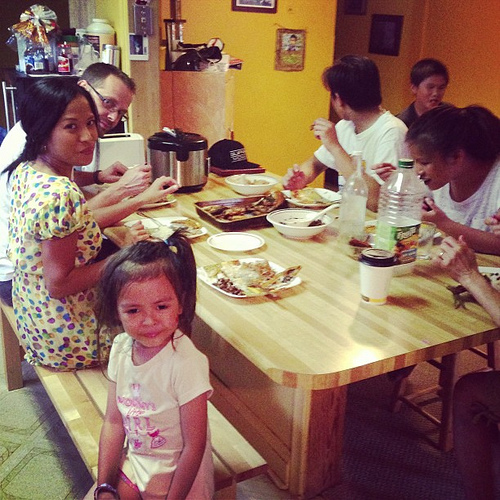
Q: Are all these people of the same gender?
A: No, they are both male and female.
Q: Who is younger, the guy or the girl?
A: The girl is younger than the guy.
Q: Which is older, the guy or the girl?
A: The guy is older than the girl.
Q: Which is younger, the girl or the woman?
A: The girl is younger than the woman.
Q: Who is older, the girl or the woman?
A: The woman is older than the girl.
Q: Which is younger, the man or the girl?
A: The girl is younger than the man.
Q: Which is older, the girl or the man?
A: The man is older than the girl.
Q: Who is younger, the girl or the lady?
A: The girl is younger than the lady.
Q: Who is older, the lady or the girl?
A: The lady is older than the girl.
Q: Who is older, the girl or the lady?
A: The lady is older than the girl.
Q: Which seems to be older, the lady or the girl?
A: The lady is older than the girl.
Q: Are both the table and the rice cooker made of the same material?
A: No, the table is made of wood and the rice cooker is made of metal.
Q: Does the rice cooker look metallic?
A: Yes, the rice cooker is metallic.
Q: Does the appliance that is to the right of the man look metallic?
A: Yes, the rice cooker is metallic.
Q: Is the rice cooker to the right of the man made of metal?
A: Yes, the rice cooker is made of metal.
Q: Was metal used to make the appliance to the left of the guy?
A: Yes, the rice cooker is made of metal.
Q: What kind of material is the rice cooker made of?
A: The rice cooker is made of metal.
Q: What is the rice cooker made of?
A: The rice cooker is made of metal.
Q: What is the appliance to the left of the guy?
A: The appliance is a rice cooker.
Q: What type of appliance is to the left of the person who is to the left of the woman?
A: The appliance is a rice cooker.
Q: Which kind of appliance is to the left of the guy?
A: The appliance is a rice cooker.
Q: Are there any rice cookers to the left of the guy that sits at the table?
A: Yes, there is a rice cooker to the left of the guy.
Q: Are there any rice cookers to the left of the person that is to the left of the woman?
A: Yes, there is a rice cooker to the left of the guy.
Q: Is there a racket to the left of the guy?
A: No, there is a rice cooker to the left of the guy.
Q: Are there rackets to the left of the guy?
A: No, there is a rice cooker to the left of the guy.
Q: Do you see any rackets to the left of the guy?
A: No, there is a rice cooker to the left of the guy.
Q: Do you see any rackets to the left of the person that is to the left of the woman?
A: No, there is a rice cooker to the left of the guy.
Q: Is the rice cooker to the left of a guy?
A: Yes, the rice cooker is to the left of a guy.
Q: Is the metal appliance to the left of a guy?
A: Yes, the rice cooker is to the left of a guy.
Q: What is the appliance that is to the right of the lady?
A: The appliance is a rice cooker.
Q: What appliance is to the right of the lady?
A: The appliance is a rice cooker.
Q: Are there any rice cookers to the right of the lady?
A: Yes, there is a rice cooker to the right of the lady.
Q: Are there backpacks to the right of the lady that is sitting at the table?
A: No, there is a rice cooker to the right of the lady.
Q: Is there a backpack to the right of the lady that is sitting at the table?
A: No, there is a rice cooker to the right of the lady.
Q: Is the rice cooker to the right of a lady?
A: Yes, the rice cooker is to the right of a lady.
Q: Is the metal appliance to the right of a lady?
A: Yes, the rice cooker is to the right of a lady.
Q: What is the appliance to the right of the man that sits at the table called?
A: The appliance is a rice cooker.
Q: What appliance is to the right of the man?
A: The appliance is a rice cooker.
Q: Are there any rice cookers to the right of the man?
A: Yes, there is a rice cooker to the right of the man.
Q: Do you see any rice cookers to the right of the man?
A: Yes, there is a rice cooker to the right of the man.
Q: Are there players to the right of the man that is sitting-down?
A: No, there is a rice cooker to the right of the man.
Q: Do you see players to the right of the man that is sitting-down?
A: No, there is a rice cooker to the right of the man.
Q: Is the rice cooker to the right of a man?
A: Yes, the rice cooker is to the right of a man.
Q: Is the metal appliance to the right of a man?
A: Yes, the rice cooker is to the right of a man.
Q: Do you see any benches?
A: Yes, there is a bench.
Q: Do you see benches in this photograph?
A: Yes, there is a bench.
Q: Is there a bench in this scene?
A: Yes, there is a bench.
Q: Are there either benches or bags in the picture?
A: Yes, there is a bench.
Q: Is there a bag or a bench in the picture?
A: Yes, there is a bench.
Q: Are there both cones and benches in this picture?
A: No, there is a bench but no cones.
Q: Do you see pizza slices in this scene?
A: No, there are no pizza slices.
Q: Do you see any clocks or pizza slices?
A: No, there are no pizza slices or clocks.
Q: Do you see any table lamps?
A: No, there are no table lamps.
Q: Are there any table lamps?
A: No, there are no table lamps.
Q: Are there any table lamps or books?
A: No, there are no table lamps or books.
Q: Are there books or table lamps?
A: No, there are no table lamps or books.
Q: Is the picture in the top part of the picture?
A: Yes, the picture is in the top of the image.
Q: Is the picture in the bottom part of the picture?
A: No, the picture is in the top of the image.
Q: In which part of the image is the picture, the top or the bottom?
A: The picture is in the top of the image.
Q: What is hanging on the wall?
A: The picture is hanging on the wall.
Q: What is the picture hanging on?
A: The picture is hanging on the wall.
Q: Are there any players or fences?
A: No, there are no players or fences.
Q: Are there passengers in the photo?
A: No, there are no passengers.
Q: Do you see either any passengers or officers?
A: No, there are no passengers or officers.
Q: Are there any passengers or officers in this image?
A: No, there are no passengers or officers.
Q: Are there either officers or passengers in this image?
A: No, there are no passengers or officers.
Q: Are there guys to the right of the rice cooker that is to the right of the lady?
A: Yes, there is a guy to the right of the rice cooker.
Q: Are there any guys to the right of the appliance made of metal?
A: Yes, there is a guy to the right of the rice cooker.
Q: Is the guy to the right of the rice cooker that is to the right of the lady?
A: Yes, the guy is to the right of the rice cooker.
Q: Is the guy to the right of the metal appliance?
A: Yes, the guy is to the right of the rice cooker.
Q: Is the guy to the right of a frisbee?
A: No, the guy is to the right of the rice cooker.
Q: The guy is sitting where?
A: The guy is sitting at the table.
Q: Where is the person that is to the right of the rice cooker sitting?
A: The guy is sitting at the table.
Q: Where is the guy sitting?
A: The guy is sitting at the table.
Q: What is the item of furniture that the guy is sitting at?
A: The piece of furniture is a table.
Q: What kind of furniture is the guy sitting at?
A: The guy is sitting at the table.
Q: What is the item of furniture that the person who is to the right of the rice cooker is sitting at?
A: The piece of furniture is a table.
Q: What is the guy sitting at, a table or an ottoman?
A: The guy is sitting at a table.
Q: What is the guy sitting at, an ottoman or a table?
A: The guy is sitting at a table.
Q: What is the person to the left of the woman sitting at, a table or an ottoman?
A: The guy is sitting at a table.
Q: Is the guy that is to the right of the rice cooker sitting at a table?
A: Yes, the guy is sitting at a table.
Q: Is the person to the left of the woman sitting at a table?
A: Yes, the guy is sitting at a table.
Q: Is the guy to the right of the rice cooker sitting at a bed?
A: No, the guy is sitting at a table.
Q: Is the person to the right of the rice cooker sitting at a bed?
A: No, the guy is sitting at a table.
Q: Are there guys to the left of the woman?
A: Yes, there is a guy to the left of the woman.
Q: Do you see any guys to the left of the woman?
A: Yes, there is a guy to the left of the woman.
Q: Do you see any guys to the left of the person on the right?
A: Yes, there is a guy to the left of the woman.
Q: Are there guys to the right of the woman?
A: No, the guy is to the left of the woman.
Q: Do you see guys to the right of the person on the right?
A: No, the guy is to the left of the woman.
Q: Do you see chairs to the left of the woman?
A: No, there is a guy to the left of the woman.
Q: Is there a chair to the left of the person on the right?
A: No, there is a guy to the left of the woman.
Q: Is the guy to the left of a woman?
A: Yes, the guy is to the left of a woman.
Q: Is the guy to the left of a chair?
A: No, the guy is to the left of a woman.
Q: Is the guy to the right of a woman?
A: No, the guy is to the left of a woman.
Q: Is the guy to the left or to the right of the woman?
A: The guy is to the left of the woman.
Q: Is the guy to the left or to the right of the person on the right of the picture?
A: The guy is to the left of the woman.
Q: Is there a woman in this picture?
A: Yes, there is a woman.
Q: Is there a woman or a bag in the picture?
A: Yes, there is a woman.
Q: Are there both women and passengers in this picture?
A: No, there is a woman but no passengers.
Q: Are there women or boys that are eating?
A: Yes, the woman is eating.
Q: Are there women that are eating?
A: Yes, there is a woman that is eating.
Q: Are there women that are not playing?
A: Yes, there is a woman that is eating.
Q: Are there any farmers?
A: No, there are no farmers.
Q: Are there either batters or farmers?
A: No, there are no farmers or batters.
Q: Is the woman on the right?
A: Yes, the woman is on the right of the image.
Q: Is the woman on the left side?
A: No, the woman is on the right of the image.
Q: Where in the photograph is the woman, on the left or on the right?
A: The woman is on the right of the image.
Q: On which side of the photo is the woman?
A: The woman is on the right of the image.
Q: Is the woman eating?
A: Yes, the woman is eating.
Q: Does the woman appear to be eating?
A: Yes, the woman is eating.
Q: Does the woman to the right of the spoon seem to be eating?
A: Yes, the woman is eating.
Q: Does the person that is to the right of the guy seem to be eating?
A: Yes, the woman is eating.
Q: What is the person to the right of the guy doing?
A: The woman is eating.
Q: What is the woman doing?
A: The woman is eating.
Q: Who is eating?
A: The woman is eating.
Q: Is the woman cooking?
A: No, the woman is eating.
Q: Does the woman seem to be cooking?
A: No, the woman is eating.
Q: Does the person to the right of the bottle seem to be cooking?
A: No, the woman is eating.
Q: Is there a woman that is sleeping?
A: No, there is a woman but she is eating.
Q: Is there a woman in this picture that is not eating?
A: No, there is a woman but she is eating.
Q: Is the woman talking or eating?
A: The woman is eating.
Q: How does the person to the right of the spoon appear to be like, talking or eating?
A: The woman is eating.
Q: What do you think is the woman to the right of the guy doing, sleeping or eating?
A: The woman is eating.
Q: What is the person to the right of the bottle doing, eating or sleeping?
A: The woman is eating.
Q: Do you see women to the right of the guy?
A: Yes, there is a woman to the right of the guy.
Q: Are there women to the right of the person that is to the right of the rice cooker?
A: Yes, there is a woman to the right of the guy.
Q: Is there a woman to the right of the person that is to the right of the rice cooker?
A: Yes, there is a woman to the right of the guy.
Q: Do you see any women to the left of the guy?
A: No, the woman is to the right of the guy.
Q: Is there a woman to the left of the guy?
A: No, the woman is to the right of the guy.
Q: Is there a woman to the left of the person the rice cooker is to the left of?
A: No, the woman is to the right of the guy.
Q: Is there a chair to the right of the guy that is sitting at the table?
A: No, there is a woman to the right of the guy.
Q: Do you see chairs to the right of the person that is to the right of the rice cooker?
A: No, there is a woman to the right of the guy.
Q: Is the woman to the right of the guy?
A: Yes, the woman is to the right of the guy.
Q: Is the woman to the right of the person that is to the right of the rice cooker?
A: Yes, the woman is to the right of the guy.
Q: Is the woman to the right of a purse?
A: No, the woman is to the right of the guy.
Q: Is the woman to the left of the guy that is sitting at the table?
A: No, the woman is to the right of the guy.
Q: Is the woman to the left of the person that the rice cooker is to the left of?
A: No, the woman is to the right of the guy.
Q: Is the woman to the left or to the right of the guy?
A: The woman is to the right of the guy.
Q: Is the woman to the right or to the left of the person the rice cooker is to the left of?
A: The woman is to the right of the guy.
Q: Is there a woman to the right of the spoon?
A: Yes, there is a woman to the right of the spoon.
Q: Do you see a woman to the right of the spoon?
A: Yes, there is a woman to the right of the spoon.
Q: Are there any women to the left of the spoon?
A: No, the woman is to the right of the spoon.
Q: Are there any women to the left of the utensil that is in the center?
A: No, the woman is to the right of the spoon.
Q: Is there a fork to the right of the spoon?
A: No, there is a woman to the right of the spoon.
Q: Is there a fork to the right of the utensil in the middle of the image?
A: No, there is a woman to the right of the spoon.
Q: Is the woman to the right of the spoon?
A: Yes, the woman is to the right of the spoon.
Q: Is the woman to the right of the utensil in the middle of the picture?
A: Yes, the woman is to the right of the spoon.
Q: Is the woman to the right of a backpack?
A: No, the woman is to the right of the spoon.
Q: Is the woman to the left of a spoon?
A: No, the woman is to the right of a spoon.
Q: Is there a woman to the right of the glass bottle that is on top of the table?
A: Yes, there is a woman to the right of the bottle.